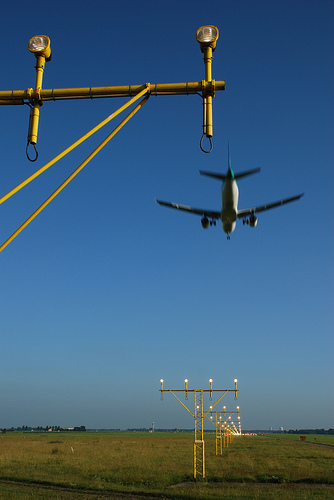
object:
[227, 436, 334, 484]
landing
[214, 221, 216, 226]
wheels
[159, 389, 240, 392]
bars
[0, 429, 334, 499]
field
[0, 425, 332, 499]
airport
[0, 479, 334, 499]
path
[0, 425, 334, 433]
background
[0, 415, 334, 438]
distance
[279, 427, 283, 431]
structures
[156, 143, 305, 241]
airplane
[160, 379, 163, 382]
lights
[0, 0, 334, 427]
sky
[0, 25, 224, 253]
towers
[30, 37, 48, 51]
lights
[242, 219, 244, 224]
wheel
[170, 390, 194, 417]
pole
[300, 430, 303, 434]
trees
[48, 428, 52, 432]
buildings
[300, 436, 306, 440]
sign